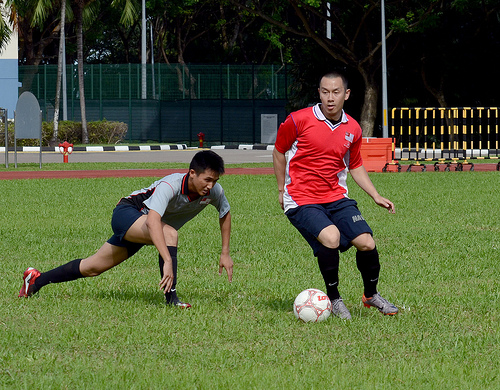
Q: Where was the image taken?
A: It was taken at the field.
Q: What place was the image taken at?
A: It was taken at the field.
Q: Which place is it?
A: It is a field.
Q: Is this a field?
A: Yes, it is a field.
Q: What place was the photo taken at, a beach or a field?
A: It was taken at a field.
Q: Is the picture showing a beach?
A: No, the picture is showing a field.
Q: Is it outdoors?
A: Yes, it is outdoors.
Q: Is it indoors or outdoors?
A: It is outdoors.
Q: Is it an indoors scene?
A: No, it is outdoors.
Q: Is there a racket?
A: No, there are no rackets.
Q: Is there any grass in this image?
A: Yes, there is grass.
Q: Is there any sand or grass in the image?
A: Yes, there is grass.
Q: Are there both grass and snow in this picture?
A: No, there is grass but no snow.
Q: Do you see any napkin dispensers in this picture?
A: No, there are no napkin dispensers.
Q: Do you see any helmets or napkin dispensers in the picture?
A: No, there are no napkin dispensers or helmets.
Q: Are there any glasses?
A: No, there are no glasses.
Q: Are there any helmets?
A: No, there are no helmets.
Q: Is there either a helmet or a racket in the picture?
A: No, there are no helmets or rackets.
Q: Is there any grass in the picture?
A: Yes, there is grass.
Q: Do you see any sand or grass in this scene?
A: Yes, there is grass.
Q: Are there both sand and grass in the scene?
A: No, there is grass but no sand.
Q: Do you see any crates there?
A: No, there are no crates.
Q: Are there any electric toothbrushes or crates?
A: No, there are no crates or electric toothbrushes.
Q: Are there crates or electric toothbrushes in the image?
A: No, there are no crates or electric toothbrushes.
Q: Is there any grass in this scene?
A: Yes, there is grass.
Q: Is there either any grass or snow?
A: Yes, there is grass.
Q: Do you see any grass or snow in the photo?
A: Yes, there is grass.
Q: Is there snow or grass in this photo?
A: Yes, there is grass.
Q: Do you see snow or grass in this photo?
A: Yes, there is grass.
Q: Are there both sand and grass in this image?
A: No, there is grass but no sand.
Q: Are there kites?
A: No, there are no kites.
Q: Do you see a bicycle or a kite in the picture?
A: No, there are no kites or bicycles.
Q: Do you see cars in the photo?
A: No, there are no cars.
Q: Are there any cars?
A: No, there are no cars.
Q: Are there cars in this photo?
A: No, there are no cars.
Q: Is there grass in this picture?
A: Yes, there is grass.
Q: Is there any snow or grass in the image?
A: Yes, there is grass.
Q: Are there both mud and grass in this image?
A: No, there is grass but no mud.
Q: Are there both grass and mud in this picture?
A: No, there is grass but no mud.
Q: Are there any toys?
A: No, there are no toys.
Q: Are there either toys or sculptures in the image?
A: No, there are no toys or sculptures.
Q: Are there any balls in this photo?
A: Yes, there is a ball.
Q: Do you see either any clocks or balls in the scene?
A: Yes, there is a ball.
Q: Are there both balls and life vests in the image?
A: No, there is a ball but no life jackets.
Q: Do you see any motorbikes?
A: No, there are no motorbikes.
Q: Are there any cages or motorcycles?
A: No, there are no motorcycles or cages.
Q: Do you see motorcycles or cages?
A: No, there are no motorcycles or cages.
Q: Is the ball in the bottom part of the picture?
A: Yes, the ball is in the bottom of the image.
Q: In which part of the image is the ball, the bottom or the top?
A: The ball is in the bottom of the image.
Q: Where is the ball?
A: The ball is on the ground.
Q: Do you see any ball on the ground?
A: Yes, there is a ball on the ground.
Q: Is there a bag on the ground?
A: No, there is a ball on the ground.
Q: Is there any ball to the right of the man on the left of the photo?
A: Yes, there is a ball to the right of the man.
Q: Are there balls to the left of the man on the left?
A: No, the ball is to the right of the man.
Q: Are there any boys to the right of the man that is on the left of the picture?
A: No, there is a ball to the right of the man.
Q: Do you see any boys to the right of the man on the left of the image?
A: No, there is a ball to the right of the man.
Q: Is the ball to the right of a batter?
A: No, the ball is to the right of the man.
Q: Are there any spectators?
A: No, there are no spectators.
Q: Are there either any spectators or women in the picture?
A: No, there are no spectators or women.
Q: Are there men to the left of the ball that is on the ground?
A: Yes, there is a man to the left of the ball.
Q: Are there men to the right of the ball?
A: No, the man is to the left of the ball.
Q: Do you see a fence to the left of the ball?
A: No, there is a man to the left of the ball.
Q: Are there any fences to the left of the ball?
A: No, there is a man to the left of the ball.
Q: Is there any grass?
A: Yes, there is grass.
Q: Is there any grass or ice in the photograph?
A: Yes, there is grass.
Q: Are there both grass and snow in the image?
A: No, there is grass but no snow.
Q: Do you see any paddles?
A: No, there are no paddles.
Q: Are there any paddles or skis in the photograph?
A: No, there are no paddles or skis.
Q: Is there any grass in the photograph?
A: Yes, there is grass.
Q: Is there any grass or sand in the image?
A: Yes, there is grass.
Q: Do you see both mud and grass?
A: No, there is grass but no mud.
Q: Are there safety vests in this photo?
A: No, there are no safety vests.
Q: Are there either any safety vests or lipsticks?
A: No, there are no safety vests or lipsticks.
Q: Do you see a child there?
A: No, there are no children.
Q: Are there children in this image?
A: No, there are no children.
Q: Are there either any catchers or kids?
A: No, there are no kids or catchers.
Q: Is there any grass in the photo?
A: Yes, there is grass.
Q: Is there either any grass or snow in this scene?
A: Yes, there is grass.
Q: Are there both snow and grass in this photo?
A: No, there is grass but no snow.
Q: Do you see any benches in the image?
A: No, there are no benches.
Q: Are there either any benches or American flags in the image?
A: No, there are no benches or American flags.